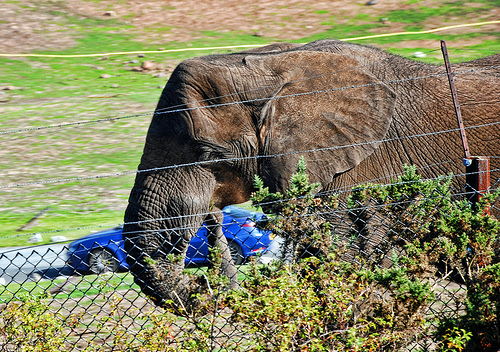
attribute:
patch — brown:
[2, 6, 76, 55]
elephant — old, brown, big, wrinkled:
[115, 32, 499, 349]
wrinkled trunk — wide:
[116, 153, 244, 325]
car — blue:
[58, 194, 282, 277]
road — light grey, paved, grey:
[0, 243, 475, 331]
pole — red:
[435, 33, 491, 346]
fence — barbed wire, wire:
[2, 56, 495, 348]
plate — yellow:
[268, 227, 281, 246]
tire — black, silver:
[84, 246, 122, 277]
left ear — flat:
[242, 48, 406, 199]